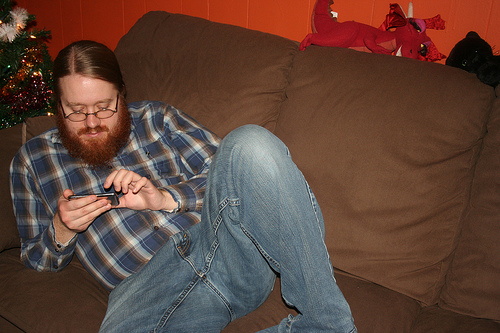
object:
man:
[10, 39, 359, 333]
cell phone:
[66, 192, 120, 207]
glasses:
[60, 94, 120, 123]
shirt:
[9, 98, 223, 291]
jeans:
[99, 123, 358, 333]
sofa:
[0, 10, 500, 333]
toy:
[299, 0, 447, 62]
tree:
[0, 1, 57, 130]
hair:
[51, 40, 129, 101]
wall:
[12, 1, 500, 65]